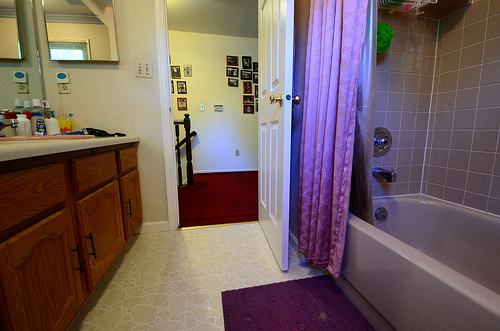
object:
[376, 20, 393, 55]
green loofah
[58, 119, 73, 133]
yellow/red cup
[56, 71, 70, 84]
night light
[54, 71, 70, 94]
bathroom outlet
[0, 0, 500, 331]
view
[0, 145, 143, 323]
brown cabinets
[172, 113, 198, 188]
railing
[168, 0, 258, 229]
hallway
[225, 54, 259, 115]
picture frames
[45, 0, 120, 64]
mirror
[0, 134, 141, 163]
countertop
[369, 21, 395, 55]
bath sponge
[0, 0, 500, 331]
bathroom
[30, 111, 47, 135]
bottle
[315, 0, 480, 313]
shower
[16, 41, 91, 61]
window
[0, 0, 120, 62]
mirror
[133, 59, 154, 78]
light switch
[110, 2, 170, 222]
wall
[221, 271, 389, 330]
rug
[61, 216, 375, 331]
floor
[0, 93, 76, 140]
grooming products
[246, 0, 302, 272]
door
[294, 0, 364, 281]
curtain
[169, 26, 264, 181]
wall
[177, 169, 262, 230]
carpet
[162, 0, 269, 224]
hall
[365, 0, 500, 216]
tile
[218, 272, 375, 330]
bath mat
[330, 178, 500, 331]
bath tub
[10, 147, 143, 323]
vanity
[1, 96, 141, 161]
counter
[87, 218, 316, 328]
tile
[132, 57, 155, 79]
switch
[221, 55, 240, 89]
posters